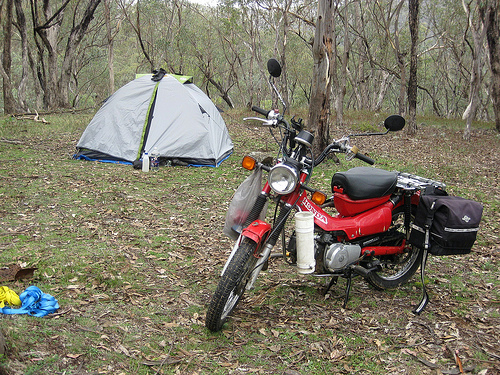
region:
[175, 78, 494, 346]
a red and black scooter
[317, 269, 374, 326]
a black kickstand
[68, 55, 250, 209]
a gray tent all closed up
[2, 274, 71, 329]
some blue fabric on the ground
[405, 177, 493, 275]
a black bag on the back of the scooter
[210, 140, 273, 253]
a plastic bag hanging on the front of the scooter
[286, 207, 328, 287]
a white cylinder basket on side of scooter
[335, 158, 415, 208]
a black seat on scooter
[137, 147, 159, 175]
a white water bottle with blue cap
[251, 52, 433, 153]
two round mirrors on scooter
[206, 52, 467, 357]
red motorcycle at campsite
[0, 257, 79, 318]
trash on ground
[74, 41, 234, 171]
tent set up at campsite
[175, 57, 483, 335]
kickstand down on motorcycle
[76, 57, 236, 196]
tent zipped closed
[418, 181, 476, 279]
black saddle bag on motorcycle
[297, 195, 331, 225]
Honda logo on motorcycle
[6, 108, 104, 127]
tree branches on ground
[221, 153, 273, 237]
plastic bag hanging on motorcycle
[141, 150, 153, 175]
plastic bottle on ground outside tent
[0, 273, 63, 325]
Two ropes, one blue, one yellow.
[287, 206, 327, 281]
A large white tube.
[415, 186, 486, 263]
A large black bag.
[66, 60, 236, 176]
A gray tent with green zipper.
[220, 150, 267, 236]
A plastic grocery bag.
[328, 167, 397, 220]
A black and red motorcycle seat.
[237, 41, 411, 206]
The front mirrors and light of a motorcycle.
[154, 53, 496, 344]
A red honda motorcycle.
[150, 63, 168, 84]
A black cloth atop the tent.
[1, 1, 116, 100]
A large outcropping of dead or dying trees.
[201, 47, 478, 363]
red motorcycle at campground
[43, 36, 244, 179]
tent in the woods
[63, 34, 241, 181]
tent at camp site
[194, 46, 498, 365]
red Honda motorcycle with black seat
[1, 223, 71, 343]
tie down straps in the grass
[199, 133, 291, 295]
plastic bag hanging off motorcycle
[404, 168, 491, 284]
black saddlebag on motorcycle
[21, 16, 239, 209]
camping tent in the woods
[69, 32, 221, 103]
motorcycle gloves on top of tent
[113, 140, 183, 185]
bottles for drinking near tent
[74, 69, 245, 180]
tent set up on grass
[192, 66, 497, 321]
red scooter on grass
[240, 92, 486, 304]
red scooter with black seat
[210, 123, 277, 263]
plastic bag hanging off of scooter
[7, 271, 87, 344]
light blue item on ground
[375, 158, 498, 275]
black and white bag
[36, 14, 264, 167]
trees behind the tent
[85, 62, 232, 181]
gray tent on blue tarp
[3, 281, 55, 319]
yellow item next to blue item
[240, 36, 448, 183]
two mirrors on handlebars